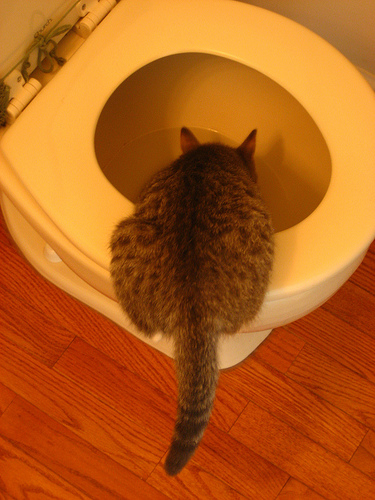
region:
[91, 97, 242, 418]
a cat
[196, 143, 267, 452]
a cat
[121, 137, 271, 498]
a cat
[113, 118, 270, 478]
the gray cat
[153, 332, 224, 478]
the tail of the cat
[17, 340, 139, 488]
the wooden floor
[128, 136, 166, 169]
the toilet water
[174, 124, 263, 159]
the cat's ears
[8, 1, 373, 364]
the white toilet bowl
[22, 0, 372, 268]
the toilet seat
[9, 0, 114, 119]
the toilet seat hinges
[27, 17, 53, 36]
the word on the toilet seat cover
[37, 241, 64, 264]
the screw cap on the toilet bowl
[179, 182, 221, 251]
back of a cat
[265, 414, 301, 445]
part of a floor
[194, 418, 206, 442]
edge of a tail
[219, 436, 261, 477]
part of a floor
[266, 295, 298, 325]
edge of a toilet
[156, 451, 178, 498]
tip of a tail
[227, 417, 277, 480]
part of a floor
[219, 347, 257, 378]
base of a toilet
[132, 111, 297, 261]
cat drinking out of toilet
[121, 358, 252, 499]
tail of the cat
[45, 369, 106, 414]
floor below the car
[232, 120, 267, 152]
ear of the cat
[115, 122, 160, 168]
water in the toilet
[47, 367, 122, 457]
pattern on the floor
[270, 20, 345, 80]
rim of the toilet seat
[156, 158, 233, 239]
gray cat on the toilet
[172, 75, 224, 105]
bowl of the toilet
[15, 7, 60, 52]
back of the toilet seat